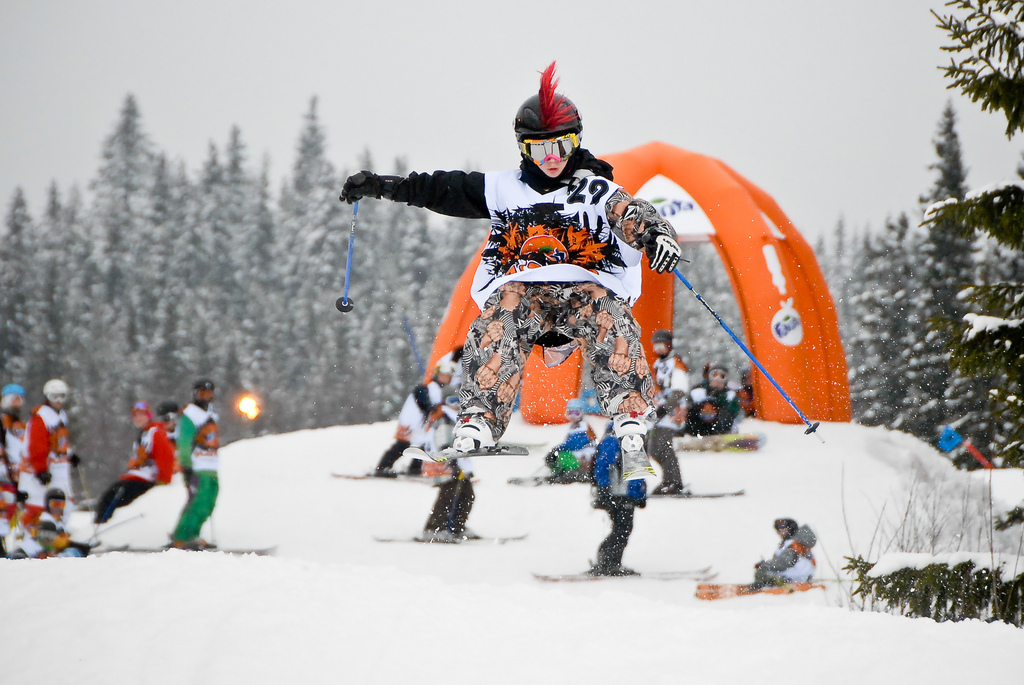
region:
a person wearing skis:
[339, 72, 821, 483]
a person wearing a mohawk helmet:
[507, 59, 585, 177]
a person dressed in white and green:
[178, 377, 220, 549]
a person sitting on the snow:
[693, 516, 829, 602]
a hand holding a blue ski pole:
[649, 228, 826, 445]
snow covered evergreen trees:
[0, 76, 1022, 449]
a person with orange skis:
[689, 518, 826, 605]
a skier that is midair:
[332, 91, 826, 483]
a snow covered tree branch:
[849, 541, 1021, 627]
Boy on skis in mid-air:
[339, 68, 830, 515]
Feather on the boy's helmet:
[536, 53, 562, 133]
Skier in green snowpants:
[118, 364, 275, 560]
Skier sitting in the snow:
[694, 510, 828, 608]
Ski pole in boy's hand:
[640, 235, 824, 439]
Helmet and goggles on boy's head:
[513, 86, 583, 182]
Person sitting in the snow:
[94, 397, 174, 528]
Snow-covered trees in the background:
[1, 80, 1020, 461]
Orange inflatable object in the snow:
[427, 141, 851, 426]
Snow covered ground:
[0, 422, 1022, 680]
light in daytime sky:
[2, 3, 1021, 257]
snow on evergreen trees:
[0, 97, 975, 503]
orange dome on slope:
[104, 137, 977, 550]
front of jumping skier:
[342, 63, 817, 485]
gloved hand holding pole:
[648, 234, 820, 438]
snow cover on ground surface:
[3, 420, 1019, 680]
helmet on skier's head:
[517, 93, 582, 188]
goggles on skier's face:
[519, 128, 580, 179]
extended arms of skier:
[335, 169, 683, 280]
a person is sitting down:
[734, 509, 824, 598]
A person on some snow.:
[145, 375, 241, 552]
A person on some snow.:
[92, 406, 181, 542]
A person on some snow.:
[151, 402, 191, 461]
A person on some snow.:
[34, 368, 110, 496]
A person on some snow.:
[160, 358, 244, 552]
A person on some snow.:
[386, 98, 643, 361]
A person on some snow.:
[568, 397, 658, 575]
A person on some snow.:
[749, 514, 823, 592]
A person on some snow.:
[413, 431, 494, 553]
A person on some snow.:
[694, 365, 745, 445]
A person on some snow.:
[27, 380, 100, 524]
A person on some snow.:
[88, 400, 166, 515]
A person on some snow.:
[155, 399, 188, 445]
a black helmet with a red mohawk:
[511, 62, 581, 140]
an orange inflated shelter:
[424, 141, 858, 430]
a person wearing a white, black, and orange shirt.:
[336, 53, 833, 510]